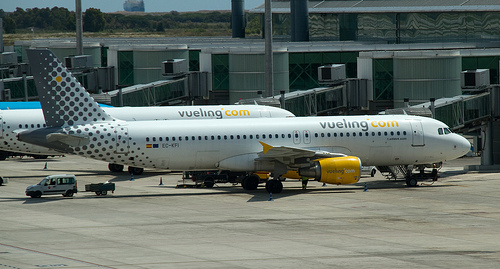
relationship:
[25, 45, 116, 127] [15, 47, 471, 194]
stabilizer on plane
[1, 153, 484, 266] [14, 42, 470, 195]
pavement covering airplane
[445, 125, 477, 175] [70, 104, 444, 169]
nose on plane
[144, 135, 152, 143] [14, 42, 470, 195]
window built into airplane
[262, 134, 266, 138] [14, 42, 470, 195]
window built into airplane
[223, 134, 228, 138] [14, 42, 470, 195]
window built into airplane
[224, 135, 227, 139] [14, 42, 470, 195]
window built into airplane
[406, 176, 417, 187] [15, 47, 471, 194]
tire on plane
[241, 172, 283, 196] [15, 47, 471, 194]
landing gear underneath plane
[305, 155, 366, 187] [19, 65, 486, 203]
engine on a plane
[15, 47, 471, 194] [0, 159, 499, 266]
plane on tarmac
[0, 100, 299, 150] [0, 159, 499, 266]
plane on tarmac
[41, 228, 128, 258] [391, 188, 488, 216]
square on square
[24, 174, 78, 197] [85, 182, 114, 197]
car dragging trailer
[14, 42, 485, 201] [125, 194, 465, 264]
airplane on ground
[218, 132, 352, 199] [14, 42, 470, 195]
wing on airplane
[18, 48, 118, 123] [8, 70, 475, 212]
airplane tail on plane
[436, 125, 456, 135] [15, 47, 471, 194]
windshield on plane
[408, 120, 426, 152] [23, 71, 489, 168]
door on plane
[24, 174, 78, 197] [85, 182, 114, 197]
car with trailer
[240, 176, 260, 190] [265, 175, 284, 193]
wheels of landing gear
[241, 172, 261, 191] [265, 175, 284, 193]
wheels of landing gear